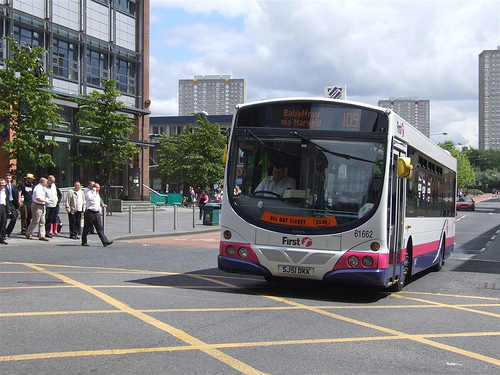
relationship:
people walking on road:
[0, 174, 118, 246] [112, 245, 219, 372]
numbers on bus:
[353, 227, 375, 237] [212, 95, 457, 292]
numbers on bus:
[340, 110, 360, 127] [212, 95, 457, 292]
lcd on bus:
[277, 107, 359, 130] [212, 95, 457, 292]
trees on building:
[17, 30, 235, 207] [7, 2, 157, 195]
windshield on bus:
[224, 98, 389, 231] [210, 89, 463, 301]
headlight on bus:
[368, 240, 380, 252] [212, 95, 457, 292]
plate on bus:
[280, 262, 315, 280] [272, 256, 320, 277]